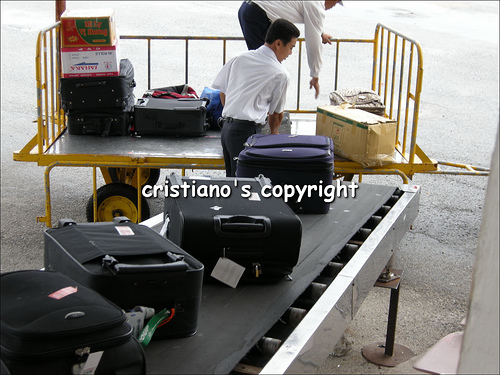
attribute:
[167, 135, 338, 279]
luggage — navy blue, black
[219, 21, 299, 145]
man — standing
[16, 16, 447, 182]
cart — metal, yellow, large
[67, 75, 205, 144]
luggage — black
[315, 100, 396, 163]
box — cardboard, long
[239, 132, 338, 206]
suitcase — blue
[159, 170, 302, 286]
suitcase — black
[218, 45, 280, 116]
shirt — white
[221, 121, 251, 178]
pants — black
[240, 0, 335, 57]
man — standing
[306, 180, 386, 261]
belt — rubber, black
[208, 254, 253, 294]
name tag — white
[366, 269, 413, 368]
steel — rusted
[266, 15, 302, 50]
hair — black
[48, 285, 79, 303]
tag — red